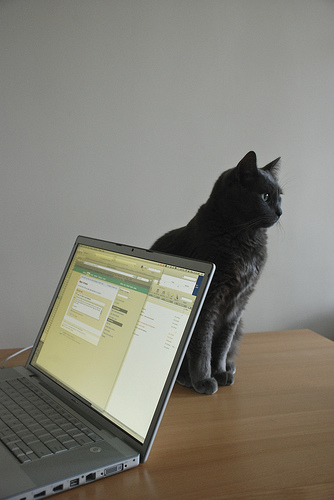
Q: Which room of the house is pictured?
A: It is an office.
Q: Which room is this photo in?
A: It is at the office.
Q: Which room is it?
A: It is an office.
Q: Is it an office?
A: Yes, it is an office.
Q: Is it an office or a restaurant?
A: It is an office.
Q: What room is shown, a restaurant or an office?
A: It is an office.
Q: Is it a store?
A: No, it is an office.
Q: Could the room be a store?
A: No, it is an office.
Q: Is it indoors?
A: Yes, it is indoors.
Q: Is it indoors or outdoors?
A: It is indoors.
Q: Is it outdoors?
A: No, it is indoors.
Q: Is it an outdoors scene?
A: No, it is indoors.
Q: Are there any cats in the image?
A: Yes, there is a cat.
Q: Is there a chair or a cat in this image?
A: Yes, there is a cat.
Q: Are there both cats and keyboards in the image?
A: Yes, there are both a cat and a keyboard.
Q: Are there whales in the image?
A: No, there are no whales.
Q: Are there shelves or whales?
A: No, there are no whales or shelves.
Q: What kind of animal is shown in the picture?
A: The animal is a cat.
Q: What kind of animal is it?
A: The animal is a cat.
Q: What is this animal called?
A: This is a cat.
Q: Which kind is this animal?
A: This is a cat.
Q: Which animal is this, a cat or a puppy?
A: This is a cat.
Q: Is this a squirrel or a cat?
A: This is a cat.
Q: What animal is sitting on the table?
A: The cat is sitting on the table.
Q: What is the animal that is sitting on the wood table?
A: The animal is a cat.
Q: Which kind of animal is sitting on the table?
A: The animal is a cat.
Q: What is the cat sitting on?
A: The cat is sitting on the table.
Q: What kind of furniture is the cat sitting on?
A: The cat is sitting on the table.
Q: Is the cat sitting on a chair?
A: No, the cat is sitting on a table.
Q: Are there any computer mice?
A: No, there are no computer mice.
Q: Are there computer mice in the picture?
A: No, there are no computer mice.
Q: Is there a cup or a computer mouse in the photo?
A: No, there are no computer mice or cups.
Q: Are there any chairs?
A: No, there are no chairs.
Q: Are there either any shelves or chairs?
A: No, there are no chairs or shelves.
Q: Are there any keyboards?
A: Yes, there is a keyboard.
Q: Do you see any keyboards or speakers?
A: Yes, there is a keyboard.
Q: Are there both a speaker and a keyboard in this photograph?
A: No, there is a keyboard but no speakers.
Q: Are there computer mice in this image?
A: No, there are no computer mice.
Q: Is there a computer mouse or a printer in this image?
A: No, there are no computer mice or printers.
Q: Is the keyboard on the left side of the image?
A: Yes, the keyboard is on the left of the image.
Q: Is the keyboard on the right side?
A: No, the keyboard is on the left of the image.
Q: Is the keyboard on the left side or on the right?
A: The keyboard is on the left of the image.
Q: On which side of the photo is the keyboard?
A: The keyboard is on the left of the image.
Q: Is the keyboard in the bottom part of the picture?
A: Yes, the keyboard is in the bottom of the image.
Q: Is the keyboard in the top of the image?
A: No, the keyboard is in the bottom of the image.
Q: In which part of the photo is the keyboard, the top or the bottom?
A: The keyboard is in the bottom of the image.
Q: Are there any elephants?
A: No, there are no elephants.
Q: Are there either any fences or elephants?
A: No, there are no elephants or fences.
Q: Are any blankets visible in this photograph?
A: No, there are no blankets.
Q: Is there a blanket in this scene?
A: No, there are no blankets.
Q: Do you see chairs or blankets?
A: No, there are no blankets or chairs.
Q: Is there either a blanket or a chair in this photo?
A: No, there are no blankets or chairs.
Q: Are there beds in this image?
A: No, there are no beds.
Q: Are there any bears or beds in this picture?
A: No, there are no beds or bears.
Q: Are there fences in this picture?
A: No, there are no fences.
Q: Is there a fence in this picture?
A: No, there are no fences.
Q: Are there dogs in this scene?
A: No, there are no dogs.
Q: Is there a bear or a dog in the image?
A: No, there are no dogs or bears.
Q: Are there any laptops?
A: Yes, there is a laptop.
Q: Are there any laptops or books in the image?
A: Yes, there is a laptop.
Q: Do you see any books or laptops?
A: Yes, there is a laptop.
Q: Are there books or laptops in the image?
A: Yes, there is a laptop.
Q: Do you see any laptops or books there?
A: Yes, there is a laptop.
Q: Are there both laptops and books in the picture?
A: No, there is a laptop but no books.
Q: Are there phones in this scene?
A: No, there are no phones.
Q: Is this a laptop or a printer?
A: This is a laptop.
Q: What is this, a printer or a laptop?
A: This is a laptop.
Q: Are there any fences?
A: No, there are no fences.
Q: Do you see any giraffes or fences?
A: No, there are no fences or giraffes.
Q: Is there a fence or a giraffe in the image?
A: No, there are no fences or giraffes.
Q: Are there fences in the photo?
A: No, there are no fences.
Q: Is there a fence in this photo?
A: No, there are no fences.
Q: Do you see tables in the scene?
A: Yes, there is a table.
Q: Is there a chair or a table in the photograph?
A: Yes, there is a table.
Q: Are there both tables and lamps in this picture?
A: No, there is a table but no lamps.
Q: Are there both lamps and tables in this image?
A: No, there is a table but no lamps.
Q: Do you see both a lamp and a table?
A: No, there is a table but no lamps.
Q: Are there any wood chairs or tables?
A: Yes, there is a wood table.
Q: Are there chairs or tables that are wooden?
A: Yes, the table is wooden.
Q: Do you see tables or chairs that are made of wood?
A: Yes, the table is made of wood.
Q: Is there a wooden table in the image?
A: Yes, there is a wood table.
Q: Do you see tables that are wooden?
A: Yes, there is a table that is wooden.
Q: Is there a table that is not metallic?
A: Yes, there is a wooden table.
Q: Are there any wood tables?
A: Yes, there is a table that is made of wood.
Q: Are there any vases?
A: No, there are no vases.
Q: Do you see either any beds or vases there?
A: No, there are no vases or beds.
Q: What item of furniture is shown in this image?
A: The piece of furniture is a table.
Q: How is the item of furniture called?
A: The piece of furniture is a table.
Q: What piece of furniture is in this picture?
A: The piece of furniture is a table.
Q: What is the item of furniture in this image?
A: The piece of furniture is a table.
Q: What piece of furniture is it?
A: The piece of furniture is a table.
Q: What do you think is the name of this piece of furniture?
A: That is a table.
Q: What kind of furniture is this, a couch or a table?
A: That is a table.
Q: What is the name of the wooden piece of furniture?
A: The piece of furniture is a table.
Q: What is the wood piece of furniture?
A: The piece of furniture is a table.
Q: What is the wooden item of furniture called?
A: The piece of furniture is a table.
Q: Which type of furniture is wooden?
A: The furniture is a table.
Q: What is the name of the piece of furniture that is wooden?
A: The piece of furniture is a table.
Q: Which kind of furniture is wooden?
A: The furniture is a table.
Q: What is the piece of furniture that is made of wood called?
A: The piece of furniture is a table.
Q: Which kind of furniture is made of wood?
A: The furniture is a table.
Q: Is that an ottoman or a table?
A: That is a table.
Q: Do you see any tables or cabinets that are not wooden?
A: No, there is a table but it is wooden.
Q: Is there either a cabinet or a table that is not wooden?
A: No, there is a table but it is wooden.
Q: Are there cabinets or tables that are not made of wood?
A: No, there is a table but it is made of wood.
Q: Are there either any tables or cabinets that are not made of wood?
A: No, there is a table but it is made of wood.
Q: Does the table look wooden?
A: Yes, the table is wooden.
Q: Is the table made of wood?
A: Yes, the table is made of wood.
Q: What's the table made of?
A: The table is made of wood.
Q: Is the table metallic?
A: No, the table is wooden.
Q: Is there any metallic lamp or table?
A: No, there is a table but it is wooden.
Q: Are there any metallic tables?
A: No, there is a table but it is wooden.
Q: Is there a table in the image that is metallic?
A: No, there is a table but it is wooden.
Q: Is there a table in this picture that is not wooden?
A: No, there is a table but it is wooden.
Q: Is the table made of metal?
A: No, the table is made of wood.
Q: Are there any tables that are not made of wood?
A: No, there is a table but it is made of wood.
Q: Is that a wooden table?
A: Yes, that is a wooden table.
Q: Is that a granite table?
A: No, that is a wooden table.